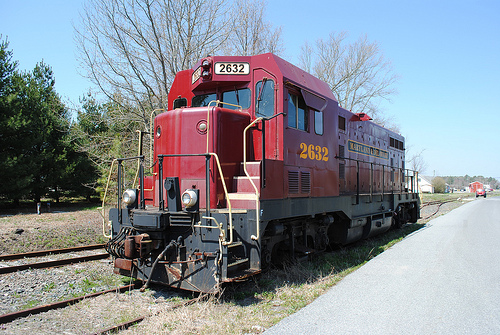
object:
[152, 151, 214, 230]
railing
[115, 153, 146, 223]
railing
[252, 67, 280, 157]
door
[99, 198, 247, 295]
front bumper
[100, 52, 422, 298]
train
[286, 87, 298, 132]
window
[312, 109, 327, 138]
window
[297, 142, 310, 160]
yellow numbers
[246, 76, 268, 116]
window wiper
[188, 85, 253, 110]
front windows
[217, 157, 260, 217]
stairs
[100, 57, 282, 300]
front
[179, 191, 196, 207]
light